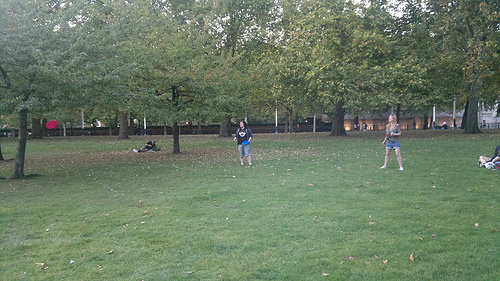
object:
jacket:
[235, 126, 254, 145]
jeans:
[385, 138, 400, 149]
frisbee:
[46, 120, 59, 129]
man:
[145, 140, 156, 153]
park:
[0, 119, 497, 281]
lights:
[344, 127, 351, 131]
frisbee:
[242, 141, 250, 145]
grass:
[1, 133, 497, 279]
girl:
[233, 119, 253, 166]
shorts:
[237, 144, 251, 158]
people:
[234, 114, 404, 171]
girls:
[133, 146, 149, 153]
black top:
[239, 126, 246, 130]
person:
[478, 145, 500, 169]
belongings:
[149, 145, 161, 152]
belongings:
[483, 157, 500, 171]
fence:
[0, 123, 500, 136]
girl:
[379, 114, 404, 171]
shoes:
[380, 165, 403, 170]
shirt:
[382, 124, 401, 144]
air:
[204, 109, 354, 126]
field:
[0, 127, 500, 281]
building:
[343, 108, 464, 131]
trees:
[0, 0, 500, 178]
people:
[132, 140, 157, 152]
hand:
[247, 140, 250, 142]